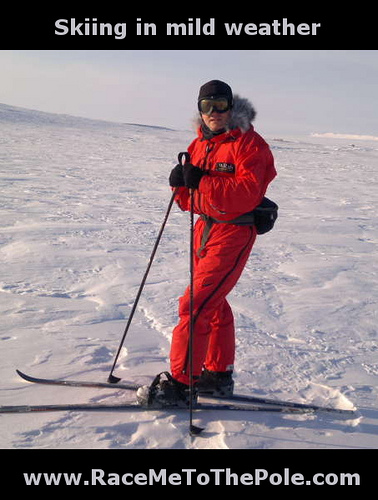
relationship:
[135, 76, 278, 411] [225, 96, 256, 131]
man has hood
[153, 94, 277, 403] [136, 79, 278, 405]
outfit on skier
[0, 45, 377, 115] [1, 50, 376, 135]
cloud in sky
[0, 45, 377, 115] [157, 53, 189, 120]
cloud in sky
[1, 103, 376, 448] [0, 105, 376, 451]
snow covering ground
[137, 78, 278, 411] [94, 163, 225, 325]
man standing on skis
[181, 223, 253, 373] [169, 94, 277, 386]
stripe on snowsuit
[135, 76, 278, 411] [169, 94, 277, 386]
man wearing snowsuit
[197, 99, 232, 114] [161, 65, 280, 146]
goggles on head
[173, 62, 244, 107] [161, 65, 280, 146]
hat on head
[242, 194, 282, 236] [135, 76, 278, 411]
bag attached to man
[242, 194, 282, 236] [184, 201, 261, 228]
bag on waist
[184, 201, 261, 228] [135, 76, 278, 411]
waist on man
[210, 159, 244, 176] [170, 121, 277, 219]
emblem on coat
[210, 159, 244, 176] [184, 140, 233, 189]
emblem on chest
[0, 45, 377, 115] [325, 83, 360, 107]
cloud in sky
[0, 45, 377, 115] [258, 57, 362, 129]
cloud in sky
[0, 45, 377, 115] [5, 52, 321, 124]
cloud in sky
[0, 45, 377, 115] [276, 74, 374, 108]
cloud in sky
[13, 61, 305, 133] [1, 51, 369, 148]
cloud in sky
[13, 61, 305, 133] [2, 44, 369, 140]
cloud in sky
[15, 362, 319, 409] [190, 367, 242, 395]
ski on foot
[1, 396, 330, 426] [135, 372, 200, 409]
ski on foot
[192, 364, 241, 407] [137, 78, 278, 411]
shoe on man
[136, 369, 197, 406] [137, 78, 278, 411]
shoe on man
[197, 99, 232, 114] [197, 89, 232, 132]
goggles on guys face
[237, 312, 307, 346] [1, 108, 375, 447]
track in snow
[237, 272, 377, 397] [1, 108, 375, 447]
track in snow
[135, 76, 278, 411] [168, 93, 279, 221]
man has coat